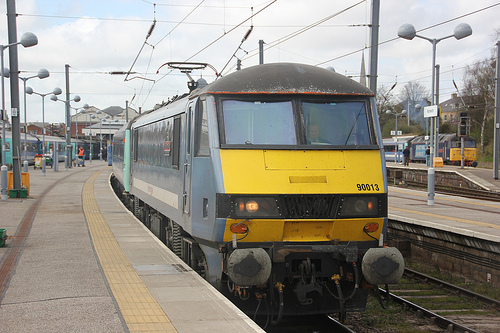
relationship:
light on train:
[236, 201, 247, 213] [105, 58, 401, 324]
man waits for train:
[378, 107, 441, 189] [105, 58, 401, 324]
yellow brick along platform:
[78, 167, 178, 331] [13, 151, 485, 314]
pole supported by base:
[5, 0, 21, 187] [8, 186, 28, 198]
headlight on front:
[227, 194, 278, 217] [219, 150, 389, 257]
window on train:
[217, 98, 298, 145] [105, 58, 401, 324]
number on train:
[355, 180, 381, 194] [105, 58, 401, 324]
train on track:
[105, 58, 401, 324] [206, 215, 500, 332]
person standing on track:
[402, 143, 411, 168] [389, 179, 496, 201]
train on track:
[105, 58, 401, 324] [206, 215, 485, 328]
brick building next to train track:
[437, 94, 492, 128] [206, 215, 500, 332]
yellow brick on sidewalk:
[78, 167, 178, 331] [0, 139, 265, 331]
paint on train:
[217, 149, 386, 244] [105, 58, 401, 324]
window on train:
[176, 100, 216, 189] [105, 58, 401, 324]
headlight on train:
[227, 194, 278, 217] [105, 58, 401, 324]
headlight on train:
[356, 196, 380, 216] [105, 58, 401, 324]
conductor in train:
[306, 98, 361, 148] [105, 58, 401, 324]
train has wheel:
[105, 58, 401, 324] [164, 222, 183, 257]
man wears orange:
[74, 144, 87, 167] [76, 146, 86, 155]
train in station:
[105, 58, 401, 324] [0, 124, 499, 331]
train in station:
[383, 135, 477, 172] [0, 124, 499, 331]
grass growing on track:
[391, 273, 461, 304] [206, 215, 500, 332]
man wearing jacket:
[74, 144, 87, 167] [76, 148, 86, 154]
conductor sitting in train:
[306, 98, 361, 148] [105, 58, 401, 324]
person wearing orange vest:
[75, 145, 85, 167] [75, 147, 85, 157]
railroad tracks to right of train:
[409, 252, 477, 327] [105, 58, 401, 324]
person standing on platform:
[402, 143, 411, 168] [386, 161, 499, 190]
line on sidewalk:
[82, 161, 178, 331] [0, 139, 265, 331]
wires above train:
[150, 4, 478, 61] [105, 58, 401, 324]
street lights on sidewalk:
[412, 18, 464, 166] [385, 157, 495, 185]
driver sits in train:
[304, 122, 332, 149] [105, 58, 401, 324]